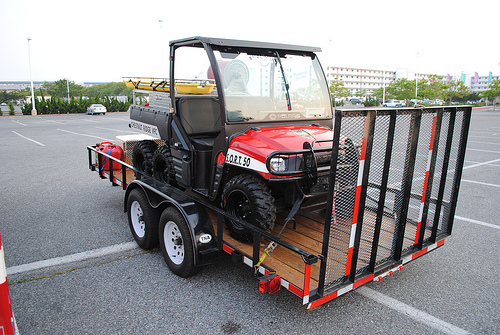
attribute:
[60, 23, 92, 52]
sky — white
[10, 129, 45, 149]
line — white 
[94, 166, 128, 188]
hazard tape — white, orange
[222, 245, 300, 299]
hazard tape — white, orange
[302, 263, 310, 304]
hazard tape — white, orange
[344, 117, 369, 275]
hazard tape — white, orange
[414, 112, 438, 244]
hazard tape — white, orange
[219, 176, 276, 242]
tire — black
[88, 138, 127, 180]
gas can — red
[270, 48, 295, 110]
wiper — black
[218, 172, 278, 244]
black tire — round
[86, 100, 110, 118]
vehicle — large, grey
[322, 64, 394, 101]
building — white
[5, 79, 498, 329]
parking lot — large, empty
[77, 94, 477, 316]
trailer — small, brown, black